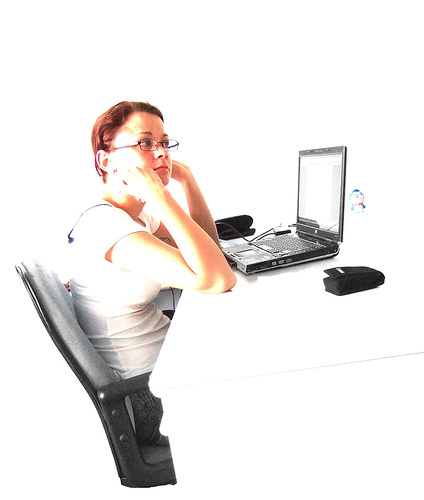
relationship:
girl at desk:
[86, 121, 182, 329] [143, 195, 422, 499]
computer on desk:
[220, 146, 345, 274] [143, 195, 422, 499]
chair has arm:
[8, 246, 219, 499] [92, 355, 188, 424]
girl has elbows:
[86, 121, 182, 329] [208, 243, 238, 298]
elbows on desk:
[208, 243, 238, 298] [143, 195, 422, 499]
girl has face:
[86, 121, 182, 329] [123, 109, 191, 193]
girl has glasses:
[86, 121, 182, 329] [98, 137, 189, 158]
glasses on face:
[98, 137, 189, 158] [123, 109, 191, 193]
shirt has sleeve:
[55, 204, 169, 386] [86, 205, 155, 271]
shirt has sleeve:
[55, 204, 169, 386] [132, 203, 167, 240]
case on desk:
[312, 252, 396, 308] [143, 195, 422, 499]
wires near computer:
[203, 222, 284, 247] [220, 146, 345, 274]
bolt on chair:
[108, 405, 122, 422] [8, 246, 219, 499]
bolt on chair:
[117, 429, 133, 448] [8, 246, 219, 499]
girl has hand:
[86, 121, 182, 329] [109, 161, 166, 203]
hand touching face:
[109, 161, 166, 203] [123, 109, 191, 193]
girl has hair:
[86, 121, 182, 329] [78, 93, 173, 177]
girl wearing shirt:
[86, 121, 182, 329] [55, 204, 169, 386]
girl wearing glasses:
[86, 121, 182, 329] [98, 137, 189, 158]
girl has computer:
[86, 121, 182, 329] [220, 146, 345, 274]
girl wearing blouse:
[86, 121, 182, 329] [60, 195, 184, 373]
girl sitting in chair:
[86, 121, 182, 329] [29, 272, 125, 409]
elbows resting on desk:
[208, 243, 238, 298] [168, 328, 275, 384]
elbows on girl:
[208, 243, 238, 298] [86, 121, 182, 329]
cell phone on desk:
[323, 263, 387, 299] [163, 306, 270, 367]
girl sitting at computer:
[86, 121, 182, 329] [259, 159, 361, 258]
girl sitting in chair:
[86, 121, 182, 329] [9, 241, 177, 482]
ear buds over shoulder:
[65, 198, 117, 243] [86, 197, 151, 269]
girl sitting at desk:
[86, 121, 182, 329] [186, 304, 390, 397]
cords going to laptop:
[241, 220, 292, 240] [295, 154, 347, 278]